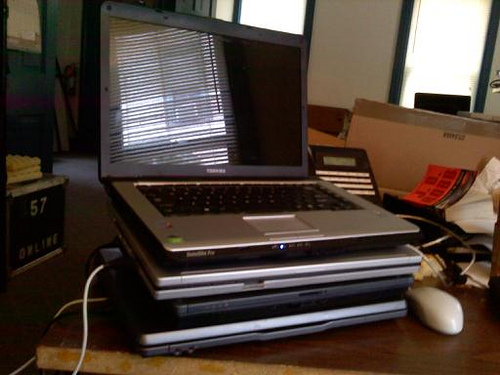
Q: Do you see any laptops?
A: Yes, there is a laptop.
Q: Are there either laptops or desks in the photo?
A: Yes, there is a laptop.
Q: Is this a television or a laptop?
A: This is a laptop.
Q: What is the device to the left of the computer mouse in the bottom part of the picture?
A: The device is a laptop.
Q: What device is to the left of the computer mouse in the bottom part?
A: The device is a laptop.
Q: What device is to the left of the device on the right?
A: The device is a laptop.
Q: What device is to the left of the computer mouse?
A: The device is a laptop.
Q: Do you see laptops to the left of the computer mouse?
A: Yes, there is a laptop to the left of the computer mouse.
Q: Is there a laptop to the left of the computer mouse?
A: Yes, there is a laptop to the left of the computer mouse.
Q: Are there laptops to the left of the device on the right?
A: Yes, there is a laptop to the left of the computer mouse.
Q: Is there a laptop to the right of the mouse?
A: No, the laptop is to the left of the mouse.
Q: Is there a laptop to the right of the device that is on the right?
A: No, the laptop is to the left of the mouse.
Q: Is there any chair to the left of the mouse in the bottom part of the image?
A: No, there is a laptop to the left of the mouse.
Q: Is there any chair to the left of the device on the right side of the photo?
A: No, there is a laptop to the left of the mouse.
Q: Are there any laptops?
A: Yes, there is a laptop.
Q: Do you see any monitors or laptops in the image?
A: Yes, there is a laptop.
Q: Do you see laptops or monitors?
A: Yes, there is a laptop.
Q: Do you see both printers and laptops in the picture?
A: No, there is a laptop but no printers.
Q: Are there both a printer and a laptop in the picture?
A: No, there is a laptop but no printers.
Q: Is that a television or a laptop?
A: That is a laptop.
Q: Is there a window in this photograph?
A: Yes, there is a window.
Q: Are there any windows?
A: Yes, there is a window.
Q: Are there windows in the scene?
A: Yes, there is a window.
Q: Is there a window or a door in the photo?
A: Yes, there is a window.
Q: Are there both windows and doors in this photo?
A: No, there is a window but no doors.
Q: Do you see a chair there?
A: No, there are no chairs.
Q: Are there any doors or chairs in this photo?
A: No, there are no chairs or doors.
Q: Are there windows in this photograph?
A: Yes, there is a window.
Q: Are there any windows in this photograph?
A: Yes, there is a window.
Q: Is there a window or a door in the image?
A: Yes, there is a window.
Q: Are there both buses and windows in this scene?
A: No, there is a window but no buses.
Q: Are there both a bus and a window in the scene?
A: No, there is a window but no buses.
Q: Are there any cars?
A: No, there are no cars.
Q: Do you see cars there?
A: No, there are no cars.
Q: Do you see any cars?
A: No, there are no cars.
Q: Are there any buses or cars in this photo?
A: No, there are no cars or buses.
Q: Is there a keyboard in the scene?
A: Yes, there is a keyboard.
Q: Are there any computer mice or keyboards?
A: Yes, there is a keyboard.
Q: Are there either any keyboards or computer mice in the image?
A: Yes, there is a keyboard.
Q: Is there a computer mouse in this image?
A: Yes, there is a computer mouse.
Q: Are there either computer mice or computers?
A: Yes, there is a computer mouse.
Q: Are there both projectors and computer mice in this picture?
A: No, there is a computer mouse but no projectors.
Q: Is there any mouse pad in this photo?
A: No, there are no mouse pads.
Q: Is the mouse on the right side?
A: Yes, the mouse is on the right of the image.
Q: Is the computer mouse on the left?
A: No, the computer mouse is on the right of the image.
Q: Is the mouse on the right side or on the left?
A: The mouse is on the right of the image.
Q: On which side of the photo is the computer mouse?
A: The computer mouse is on the right of the image.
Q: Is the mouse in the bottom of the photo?
A: Yes, the mouse is in the bottom of the image.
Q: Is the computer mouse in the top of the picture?
A: No, the computer mouse is in the bottom of the image.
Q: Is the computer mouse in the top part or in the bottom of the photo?
A: The computer mouse is in the bottom of the image.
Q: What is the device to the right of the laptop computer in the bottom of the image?
A: The device is a computer mouse.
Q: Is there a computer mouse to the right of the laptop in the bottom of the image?
A: Yes, there is a computer mouse to the right of the laptop.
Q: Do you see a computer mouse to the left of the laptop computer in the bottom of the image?
A: No, the computer mouse is to the right of the laptop.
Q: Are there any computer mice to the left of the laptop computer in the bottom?
A: No, the computer mouse is to the right of the laptop.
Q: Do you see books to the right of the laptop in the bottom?
A: No, there is a computer mouse to the right of the laptop.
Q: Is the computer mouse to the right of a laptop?
A: Yes, the computer mouse is to the right of a laptop.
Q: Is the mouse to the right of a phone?
A: No, the mouse is to the right of a laptop.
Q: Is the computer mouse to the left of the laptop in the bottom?
A: No, the computer mouse is to the right of the laptop computer.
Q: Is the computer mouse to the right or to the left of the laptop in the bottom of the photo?
A: The computer mouse is to the right of the laptop.